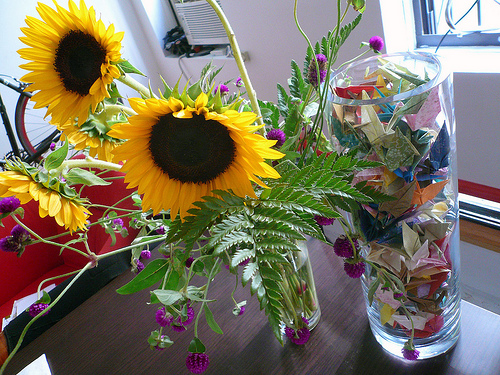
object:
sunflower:
[13, 0, 125, 130]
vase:
[277, 246, 322, 336]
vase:
[317, 49, 465, 361]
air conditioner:
[172, 0, 232, 46]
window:
[406, 0, 499, 47]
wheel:
[13, 81, 67, 168]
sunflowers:
[107, 88, 288, 225]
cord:
[185, 39, 218, 59]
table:
[14, 229, 499, 374]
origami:
[401, 83, 441, 132]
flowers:
[342, 258, 367, 279]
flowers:
[183, 346, 210, 374]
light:
[444, 0, 497, 25]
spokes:
[0, 74, 61, 167]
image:
[0, 0, 499, 373]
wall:
[242, 1, 282, 52]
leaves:
[178, 159, 345, 344]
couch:
[0, 151, 95, 238]